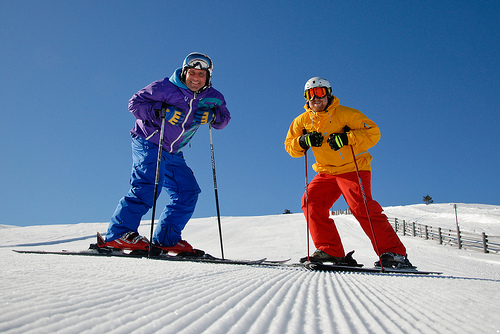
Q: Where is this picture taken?
A: A ski slope.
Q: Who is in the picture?
A: Two men.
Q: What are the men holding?
A: Poles.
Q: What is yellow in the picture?
A: A jacket.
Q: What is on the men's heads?
A: Goggles.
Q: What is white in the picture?
A: Snow.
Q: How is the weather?
A: Clear.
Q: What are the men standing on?
A: Snow.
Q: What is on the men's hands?
A: Gloves.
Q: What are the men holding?
A: Ski poles.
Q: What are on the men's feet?
A: Skis.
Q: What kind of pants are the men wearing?
A: Snow pants.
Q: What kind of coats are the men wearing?
A: Snow jackets.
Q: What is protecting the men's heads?
A: Helmets.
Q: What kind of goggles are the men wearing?
A: Snow goggles.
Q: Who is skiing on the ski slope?
A: Two men.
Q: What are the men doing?
A: Skiing.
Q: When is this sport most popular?
A: Winter.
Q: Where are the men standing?
A: Ski slope.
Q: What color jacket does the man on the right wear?
A: Yellow.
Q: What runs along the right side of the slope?
A: Fence.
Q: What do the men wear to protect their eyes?
A: Goggles.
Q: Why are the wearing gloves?
A: For warmth.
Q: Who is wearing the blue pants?
A: Man on left.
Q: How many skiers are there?
A: 2.